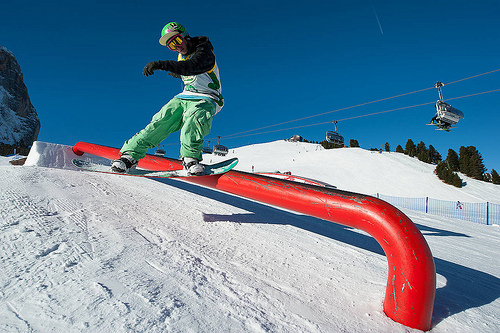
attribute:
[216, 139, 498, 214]
hill — snowy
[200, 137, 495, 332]
hill — snowy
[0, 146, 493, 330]
hill — snowy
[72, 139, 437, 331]
pole — orange, metal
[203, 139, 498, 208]
hill — snowy